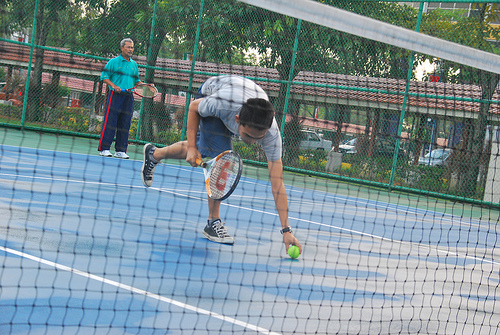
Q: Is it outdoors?
A: Yes, it is outdoors.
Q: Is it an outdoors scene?
A: Yes, it is outdoors.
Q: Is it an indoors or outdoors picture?
A: It is outdoors.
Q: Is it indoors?
A: No, it is outdoors.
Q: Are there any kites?
A: No, there are no kites.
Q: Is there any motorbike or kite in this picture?
A: No, there are no kites or motorcycles.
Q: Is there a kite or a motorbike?
A: No, there are no kites or motorcycles.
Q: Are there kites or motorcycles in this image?
A: No, there are no kites or motorcycles.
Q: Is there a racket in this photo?
A: Yes, there is a racket.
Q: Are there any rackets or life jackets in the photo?
A: Yes, there is a racket.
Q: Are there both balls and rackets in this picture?
A: Yes, there are both a racket and a ball.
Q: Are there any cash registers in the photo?
A: No, there are no cash registers.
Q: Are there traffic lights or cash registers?
A: No, there are no cash registers or traffic lights.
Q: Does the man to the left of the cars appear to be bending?
A: Yes, the man is bending.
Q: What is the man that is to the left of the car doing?
A: The man is bending.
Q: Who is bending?
A: The man is bending.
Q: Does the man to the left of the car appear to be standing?
A: No, the man is bending.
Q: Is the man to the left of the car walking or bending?
A: The man is bending.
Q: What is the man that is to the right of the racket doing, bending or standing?
A: The man is bending.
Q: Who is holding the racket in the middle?
A: The man is holding the tennis racket.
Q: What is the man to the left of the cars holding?
A: The man is holding the tennis racket.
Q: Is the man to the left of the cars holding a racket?
A: Yes, the man is holding a racket.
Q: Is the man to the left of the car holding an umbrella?
A: No, the man is holding a racket.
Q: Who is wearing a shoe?
A: The man is wearing a shoe.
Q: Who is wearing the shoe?
A: The man is wearing a shoe.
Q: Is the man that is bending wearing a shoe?
A: Yes, the man is wearing a shoe.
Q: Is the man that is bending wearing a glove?
A: No, the man is wearing a shoe.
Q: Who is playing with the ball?
A: The man is playing with the ball.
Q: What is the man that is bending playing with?
A: The man is playing with a ball.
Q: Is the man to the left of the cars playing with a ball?
A: Yes, the man is playing with a ball.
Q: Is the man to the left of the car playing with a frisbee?
A: No, the man is playing with a ball.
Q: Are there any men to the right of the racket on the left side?
A: Yes, there is a man to the right of the tennis racket.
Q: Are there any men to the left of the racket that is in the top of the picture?
A: No, the man is to the right of the racket.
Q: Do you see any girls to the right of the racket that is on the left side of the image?
A: No, there is a man to the right of the racket.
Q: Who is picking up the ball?
A: The man is picking up the ball.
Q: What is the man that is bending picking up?
A: The man is picking up the ball.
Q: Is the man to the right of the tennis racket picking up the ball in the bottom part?
A: Yes, the man is picking up the ball.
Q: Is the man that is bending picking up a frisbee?
A: No, the man is picking up the ball.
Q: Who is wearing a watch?
A: The man is wearing a watch.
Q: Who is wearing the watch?
A: The man is wearing a watch.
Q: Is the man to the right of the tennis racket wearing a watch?
A: Yes, the man is wearing a watch.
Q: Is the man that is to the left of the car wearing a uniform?
A: No, the man is wearing a watch.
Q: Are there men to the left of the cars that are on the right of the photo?
A: Yes, there is a man to the left of the cars.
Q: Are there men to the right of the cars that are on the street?
A: No, the man is to the left of the cars.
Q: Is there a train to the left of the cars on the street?
A: No, there is a man to the left of the cars.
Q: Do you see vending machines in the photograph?
A: No, there are no vending machines.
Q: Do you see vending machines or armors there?
A: No, there are no vending machines or armors.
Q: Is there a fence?
A: Yes, there is a fence.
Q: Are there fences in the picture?
A: Yes, there is a fence.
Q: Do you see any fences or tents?
A: Yes, there is a fence.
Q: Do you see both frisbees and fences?
A: No, there is a fence but no frisbees.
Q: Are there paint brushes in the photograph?
A: No, there are no paint brushes.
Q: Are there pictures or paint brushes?
A: No, there are no paint brushes or pictures.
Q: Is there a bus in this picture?
A: No, there are no buses.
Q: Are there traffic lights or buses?
A: No, there are no buses or traffic lights.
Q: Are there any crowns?
A: No, there are no crowns.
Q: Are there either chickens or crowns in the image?
A: No, there are no crowns or chickens.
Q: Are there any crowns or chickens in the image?
A: No, there are no crowns or chickens.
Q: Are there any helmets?
A: No, there are no helmets.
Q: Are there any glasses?
A: No, there are no glasses.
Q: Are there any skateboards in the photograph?
A: No, there are no skateboards.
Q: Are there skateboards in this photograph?
A: No, there are no skateboards.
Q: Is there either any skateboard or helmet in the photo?
A: No, there are no skateboards or helmets.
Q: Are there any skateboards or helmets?
A: No, there are no skateboards or helmets.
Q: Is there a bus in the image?
A: No, there are no buses.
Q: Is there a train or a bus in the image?
A: No, there are no buses or trains.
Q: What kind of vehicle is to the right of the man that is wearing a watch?
A: The vehicle is a car.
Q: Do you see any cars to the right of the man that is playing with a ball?
A: Yes, there is a car to the right of the man.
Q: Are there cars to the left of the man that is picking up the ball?
A: No, the car is to the right of the man.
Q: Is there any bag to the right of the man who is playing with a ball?
A: No, there is a car to the right of the man.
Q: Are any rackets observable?
A: Yes, there is a racket.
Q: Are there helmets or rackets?
A: Yes, there is a racket.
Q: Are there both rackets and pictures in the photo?
A: No, there is a racket but no pictures.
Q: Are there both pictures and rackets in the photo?
A: No, there is a racket but no pictures.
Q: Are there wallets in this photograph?
A: No, there are no wallets.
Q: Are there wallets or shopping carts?
A: No, there are no wallets or shopping carts.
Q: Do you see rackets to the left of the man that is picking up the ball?
A: Yes, there is a racket to the left of the man.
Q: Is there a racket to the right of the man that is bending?
A: No, the racket is to the left of the man.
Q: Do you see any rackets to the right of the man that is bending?
A: No, the racket is to the left of the man.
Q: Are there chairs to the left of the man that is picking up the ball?
A: No, there is a racket to the left of the man.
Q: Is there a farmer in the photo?
A: No, there are no farmers.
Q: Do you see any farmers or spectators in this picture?
A: No, there are no farmers or spectators.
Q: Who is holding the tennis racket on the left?
A: The man is holding the tennis racket.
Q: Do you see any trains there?
A: No, there are no trains.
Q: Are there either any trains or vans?
A: No, there are no trains or vans.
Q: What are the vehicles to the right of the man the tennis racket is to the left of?
A: The vehicles are cars.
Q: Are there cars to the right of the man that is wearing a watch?
A: Yes, there are cars to the right of the man.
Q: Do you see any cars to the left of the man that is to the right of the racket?
A: No, the cars are to the right of the man.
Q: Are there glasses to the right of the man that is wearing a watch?
A: No, there are cars to the right of the man.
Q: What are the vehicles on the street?
A: The vehicles are cars.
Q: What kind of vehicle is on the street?
A: The vehicles are cars.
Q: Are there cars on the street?
A: Yes, there are cars on the street.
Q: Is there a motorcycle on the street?
A: No, there are cars on the street.